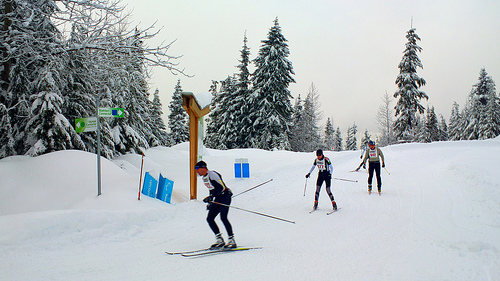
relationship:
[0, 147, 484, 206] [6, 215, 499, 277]
snow covering ground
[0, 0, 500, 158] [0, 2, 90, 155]
snow covering tree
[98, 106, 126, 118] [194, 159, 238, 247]
sign behind skier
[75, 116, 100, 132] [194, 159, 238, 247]
sign behind skier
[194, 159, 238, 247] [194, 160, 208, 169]
skier wearing cap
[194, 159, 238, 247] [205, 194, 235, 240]
skier wearing pants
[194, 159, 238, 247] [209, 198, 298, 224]
skier holding ski pole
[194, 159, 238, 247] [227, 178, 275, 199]
skier holding ski pole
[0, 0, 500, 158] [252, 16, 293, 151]
snow covering tree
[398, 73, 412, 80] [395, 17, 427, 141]
snow covering tree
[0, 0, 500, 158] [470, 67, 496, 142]
snow covering tree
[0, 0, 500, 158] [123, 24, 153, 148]
snow covering tree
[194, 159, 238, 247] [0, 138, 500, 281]
skier in snow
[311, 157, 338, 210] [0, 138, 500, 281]
skier in snow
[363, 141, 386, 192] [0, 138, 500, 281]
skier in snow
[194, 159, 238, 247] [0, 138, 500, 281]
skier skiing in snow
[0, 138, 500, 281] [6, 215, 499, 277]
snow covering ground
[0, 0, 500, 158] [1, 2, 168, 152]
snow covering trees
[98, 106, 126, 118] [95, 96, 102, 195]
sign on pole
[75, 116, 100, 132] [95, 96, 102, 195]
sign on pole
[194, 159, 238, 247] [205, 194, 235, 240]
skier in black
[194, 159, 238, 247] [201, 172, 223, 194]
skier in white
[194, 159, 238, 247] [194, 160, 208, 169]
skier wearing gear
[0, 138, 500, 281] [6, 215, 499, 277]
snow on ground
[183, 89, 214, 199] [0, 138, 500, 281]
mail box sticking out of snow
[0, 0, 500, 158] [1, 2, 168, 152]
snow on trees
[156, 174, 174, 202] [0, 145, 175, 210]
flag in snow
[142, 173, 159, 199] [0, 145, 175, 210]
flag in snow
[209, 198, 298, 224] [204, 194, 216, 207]
ski pole in hand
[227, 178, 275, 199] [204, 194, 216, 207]
ski pole in hand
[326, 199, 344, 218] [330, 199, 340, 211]
ski under foot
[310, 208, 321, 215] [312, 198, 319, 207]
ski under foot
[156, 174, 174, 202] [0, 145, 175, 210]
flag sticking in snow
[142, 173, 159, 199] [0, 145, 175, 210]
flag sticking in snow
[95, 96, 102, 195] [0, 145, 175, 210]
pole on slope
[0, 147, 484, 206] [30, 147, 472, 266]
snow covering slope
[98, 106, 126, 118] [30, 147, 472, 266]
sign on slope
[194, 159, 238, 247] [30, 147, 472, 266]
skier on slope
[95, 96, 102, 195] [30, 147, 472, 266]
pole on slope